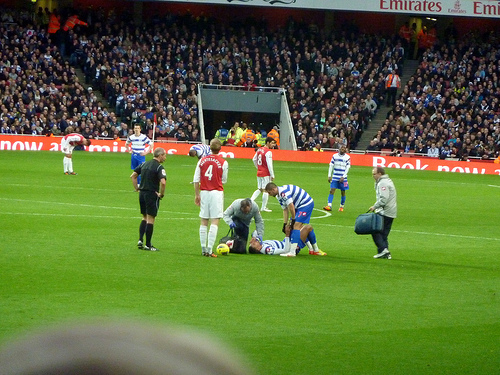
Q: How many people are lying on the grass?
A: One.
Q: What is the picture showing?
A: A man who may be injured.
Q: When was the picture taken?
A: During a game.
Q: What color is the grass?
A: Green.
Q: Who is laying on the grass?
A: A man.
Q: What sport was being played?
A: Soccer.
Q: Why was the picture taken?
A: To capture the man who's injured.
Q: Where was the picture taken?
A: On the soccer field.